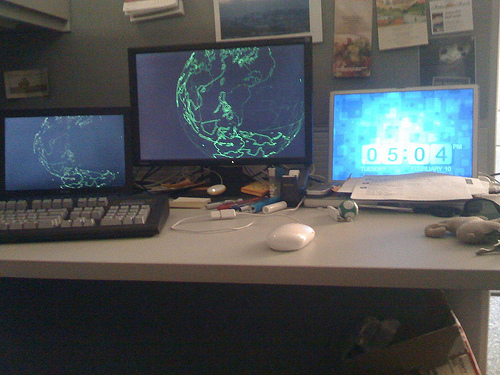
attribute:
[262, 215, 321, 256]
mouse — white, cordless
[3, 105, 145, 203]
monitor — on, black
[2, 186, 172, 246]
keyboard — large, black, white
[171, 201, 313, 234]
wire — thin, white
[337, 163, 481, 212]
paper — thin, small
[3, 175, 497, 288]
desk — white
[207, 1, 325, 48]
picture — hanging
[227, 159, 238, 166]
light — tiny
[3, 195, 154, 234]
keys — grey, gray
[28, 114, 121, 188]
globe — represented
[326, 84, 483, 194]
computer — white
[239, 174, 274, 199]
post-it notes — yellow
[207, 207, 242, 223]
white out — small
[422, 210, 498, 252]
elephant — stuffed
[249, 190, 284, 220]
highlighter — blue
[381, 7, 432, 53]
calendar — white